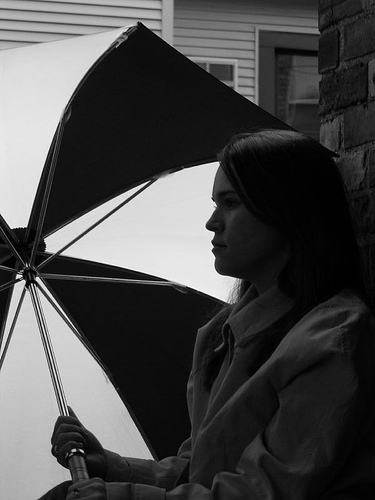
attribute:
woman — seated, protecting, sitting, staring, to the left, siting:
[41, 129, 374, 484]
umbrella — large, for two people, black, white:
[0, 20, 336, 497]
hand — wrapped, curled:
[48, 408, 149, 484]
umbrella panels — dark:
[36, 27, 335, 232]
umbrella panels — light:
[40, 163, 271, 302]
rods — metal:
[0, 115, 172, 364]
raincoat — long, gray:
[180, 285, 362, 500]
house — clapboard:
[1, 6, 370, 111]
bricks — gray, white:
[317, 12, 373, 202]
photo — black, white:
[0, 6, 368, 498]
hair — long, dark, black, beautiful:
[223, 136, 359, 378]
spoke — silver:
[11, 132, 103, 485]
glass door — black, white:
[263, 27, 337, 150]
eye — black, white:
[213, 192, 238, 209]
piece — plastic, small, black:
[0, 227, 44, 277]